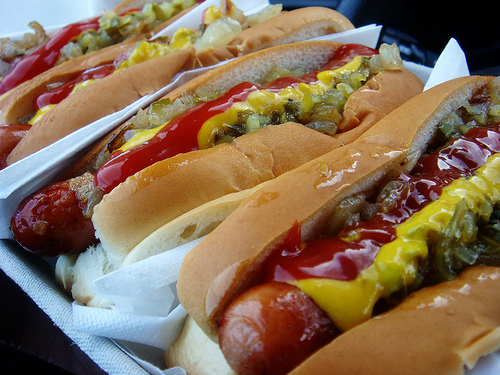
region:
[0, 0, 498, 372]
Hot dogs lined up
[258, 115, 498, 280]
Ketchup poured on a hotdog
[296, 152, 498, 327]
Mustard squirted on a hotdog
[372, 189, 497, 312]
Relish scooped on a hotdog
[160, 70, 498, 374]
Hotdog bun filled with food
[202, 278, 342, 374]
Hotdog sticking out of a bun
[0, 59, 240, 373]
White napkin around hotdog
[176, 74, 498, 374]
Hotdog with mustard, ketchup and relish on top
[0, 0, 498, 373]
Freshly made hotdogs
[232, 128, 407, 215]
Vinegar from relish made the bun wet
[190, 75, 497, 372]
this is a hot dog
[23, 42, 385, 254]
this is a hot dog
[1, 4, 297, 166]
this is a hot dog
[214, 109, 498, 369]
a sausage in a hot dog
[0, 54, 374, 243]
a sausage in a hot dog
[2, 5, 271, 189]
a sausage in a hot dog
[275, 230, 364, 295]
this is tomato sauce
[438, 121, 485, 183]
this is tomato sauce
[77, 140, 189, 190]
this is tomato sauce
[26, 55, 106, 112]
this is tomato sauce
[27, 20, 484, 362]
A row of hot dogs in their buns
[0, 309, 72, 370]
A black wooden table beneath the food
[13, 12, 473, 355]
A line of food served in napkins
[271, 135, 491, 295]
Ketchup and mustard on the hot dog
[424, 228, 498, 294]
Relish in the hot dog bun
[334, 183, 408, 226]
Chopped onions in the ketchup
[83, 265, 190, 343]
A plain white napkin by the hotdog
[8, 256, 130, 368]
A white serving tray below the food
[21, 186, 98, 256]
A hot dog sticking out of its bun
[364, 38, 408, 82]
Chopped onion on top of the bun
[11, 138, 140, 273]
This is a snack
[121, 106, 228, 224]
This is a snack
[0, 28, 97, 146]
This is a snack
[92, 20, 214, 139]
This is a snack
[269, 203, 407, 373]
This is a snack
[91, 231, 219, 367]
This is a snack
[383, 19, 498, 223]
This is a snack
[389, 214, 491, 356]
This is a snack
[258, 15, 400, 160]
This is a snack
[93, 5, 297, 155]
This is a snack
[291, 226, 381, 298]
this is a souce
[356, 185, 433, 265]
this is a souce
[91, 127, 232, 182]
this is a souce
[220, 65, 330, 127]
this is a souce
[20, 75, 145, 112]
this is a souce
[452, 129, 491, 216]
this is a souce